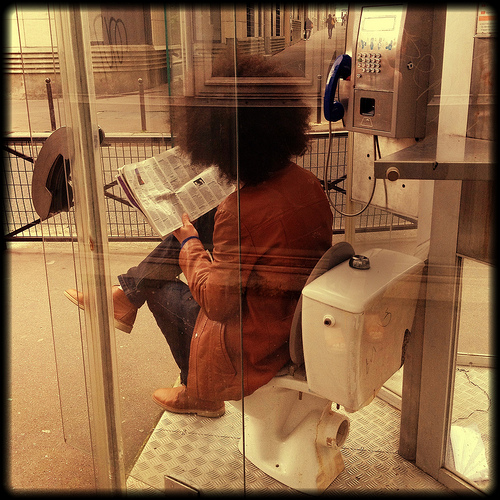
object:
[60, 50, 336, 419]
lady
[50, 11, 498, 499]
telephone booth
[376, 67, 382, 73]
buttons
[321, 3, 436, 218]
phone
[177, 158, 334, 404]
pullover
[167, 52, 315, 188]
hair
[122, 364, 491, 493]
floor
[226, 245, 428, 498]
toilet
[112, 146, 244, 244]
newspaper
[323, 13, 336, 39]
person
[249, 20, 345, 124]
sidewalk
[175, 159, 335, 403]
jacket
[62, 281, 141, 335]
boots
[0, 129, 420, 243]
fence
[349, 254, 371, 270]
knob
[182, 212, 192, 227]
thumb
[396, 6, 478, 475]
wall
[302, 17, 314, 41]
people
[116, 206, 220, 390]
jeans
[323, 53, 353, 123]
phone receiver